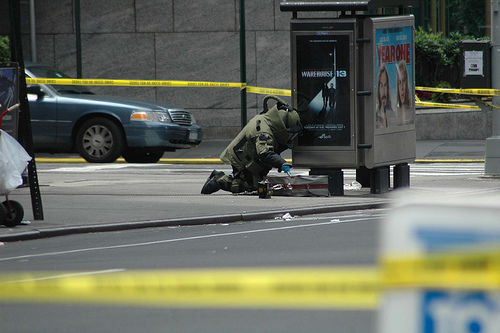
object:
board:
[362, 13, 415, 169]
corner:
[256, 200, 390, 219]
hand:
[281, 165, 291, 174]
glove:
[281, 165, 292, 175]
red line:
[269, 184, 329, 189]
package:
[266, 175, 331, 198]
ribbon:
[25, 77, 291, 96]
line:
[115, 217, 359, 248]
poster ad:
[294, 35, 351, 147]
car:
[23, 61, 204, 164]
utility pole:
[484, 0, 499, 175]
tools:
[257, 178, 284, 200]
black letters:
[25, 77, 241, 88]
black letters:
[418, 87, 494, 94]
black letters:
[433, 104, 468, 108]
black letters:
[11, 272, 359, 297]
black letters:
[403, 256, 494, 279]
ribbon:
[415, 86, 499, 109]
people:
[376, 60, 414, 127]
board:
[457, 39, 492, 89]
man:
[199, 109, 302, 195]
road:
[28, 159, 483, 175]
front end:
[58, 93, 203, 161]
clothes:
[200, 94, 304, 195]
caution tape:
[0, 249, 500, 311]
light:
[191, 115, 197, 124]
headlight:
[129, 110, 170, 122]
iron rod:
[9, 25, 44, 221]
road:
[197, 223, 361, 248]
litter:
[274, 212, 299, 222]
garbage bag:
[0, 129, 35, 196]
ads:
[374, 21, 413, 129]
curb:
[0, 220, 152, 243]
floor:
[0, 248, 368, 325]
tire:
[76, 117, 127, 163]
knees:
[242, 180, 261, 193]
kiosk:
[279, 0, 417, 196]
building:
[0, 0, 500, 140]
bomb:
[262, 175, 329, 198]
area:
[0, 1, 499, 331]